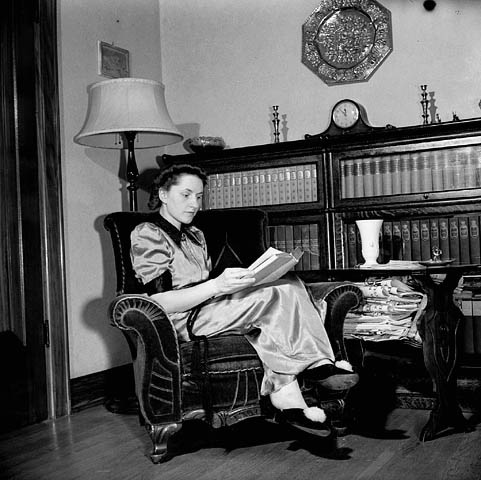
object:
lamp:
[67, 77, 186, 213]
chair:
[100, 209, 362, 461]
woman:
[125, 164, 358, 435]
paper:
[356, 283, 388, 299]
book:
[419, 152, 430, 191]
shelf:
[330, 136, 481, 207]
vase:
[352, 220, 383, 270]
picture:
[96, 40, 130, 77]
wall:
[156, 0, 480, 153]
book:
[236, 244, 305, 293]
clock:
[332, 98, 361, 129]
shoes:
[293, 361, 358, 390]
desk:
[294, 266, 473, 441]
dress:
[126, 218, 338, 400]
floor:
[0, 391, 480, 480]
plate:
[297, 0, 392, 89]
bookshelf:
[327, 202, 481, 275]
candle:
[417, 85, 431, 123]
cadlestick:
[270, 103, 281, 142]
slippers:
[303, 366, 361, 396]